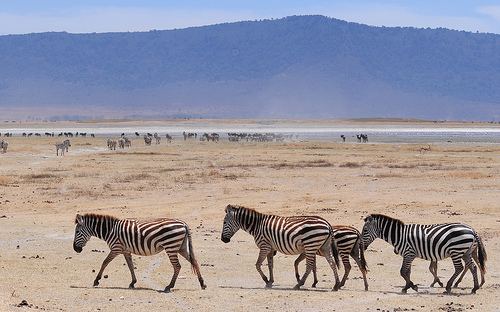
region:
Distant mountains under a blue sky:
[1, 2, 498, 129]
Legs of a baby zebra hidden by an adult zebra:
[430, 256, 488, 289]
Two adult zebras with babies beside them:
[220, 203, 488, 293]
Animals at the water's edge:
[2, 124, 372, 144]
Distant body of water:
[2, 124, 499, 141]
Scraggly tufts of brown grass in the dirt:
[7, 158, 498, 201]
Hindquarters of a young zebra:
[333, 222, 370, 291]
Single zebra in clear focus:
[71, 209, 208, 294]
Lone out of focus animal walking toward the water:
[53, 139, 75, 158]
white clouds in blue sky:
[10, 1, 61, 41]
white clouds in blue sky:
[47, 5, 108, 45]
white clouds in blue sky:
[127, 3, 188, 34]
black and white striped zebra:
[220, 195, 320, 282]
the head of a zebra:
[67, 199, 118, 263]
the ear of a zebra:
[63, 204, 103, 229]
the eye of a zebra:
[67, 212, 99, 241]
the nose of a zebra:
[61, 220, 111, 257]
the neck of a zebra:
[81, 202, 126, 250]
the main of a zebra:
[82, 201, 129, 235]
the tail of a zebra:
[171, 210, 220, 277]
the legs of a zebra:
[85, 239, 217, 295]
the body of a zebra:
[61, 184, 236, 271]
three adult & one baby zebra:
[59, 185, 488, 307]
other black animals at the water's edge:
[14, 125, 99, 138]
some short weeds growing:
[31, 163, 336, 191]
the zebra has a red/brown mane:
[83, 207, 127, 221]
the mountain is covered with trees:
[110, 18, 470, 90]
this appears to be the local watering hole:
[74, 108, 485, 155]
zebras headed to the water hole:
[40, 125, 137, 173]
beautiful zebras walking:
[66, 203, 492, 305]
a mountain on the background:
[1, 8, 497, 122]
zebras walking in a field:
[53, 174, 498, 301]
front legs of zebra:
[91, 245, 141, 292]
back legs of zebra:
[160, 246, 205, 291]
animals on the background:
[1, 118, 377, 165]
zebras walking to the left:
[53, 189, 495, 305]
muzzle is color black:
[67, 235, 84, 254]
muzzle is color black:
[217, 230, 230, 244]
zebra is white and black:
[366, 208, 405, 228]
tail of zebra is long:
[181, 219, 204, 279]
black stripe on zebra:
[444, 235, 471, 252]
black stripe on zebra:
[438, 228, 472, 254]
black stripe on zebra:
[303, 232, 327, 242]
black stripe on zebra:
[334, 230, 351, 242]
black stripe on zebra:
[336, 234, 357, 248]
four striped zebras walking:
[72, 208, 487, 295]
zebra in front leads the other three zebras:
[72, 211, 206, 294]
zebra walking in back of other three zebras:
[358, 210, 490, 295]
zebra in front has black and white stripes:
[72, 211, 205, 294]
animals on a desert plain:
[0, 118, 499, 309]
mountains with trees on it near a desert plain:
[1, 10, 496, 127]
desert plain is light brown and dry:
[0, 135, 499, 310]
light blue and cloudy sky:
[1, 2, 498, 29]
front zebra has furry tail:
[183, 219, 203, 279]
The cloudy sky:
[5, 1, 498, 56]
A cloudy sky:
[2, 1, 496, 28]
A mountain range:
[3, 25, 498, 140]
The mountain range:
[7, 15, 496, 142]